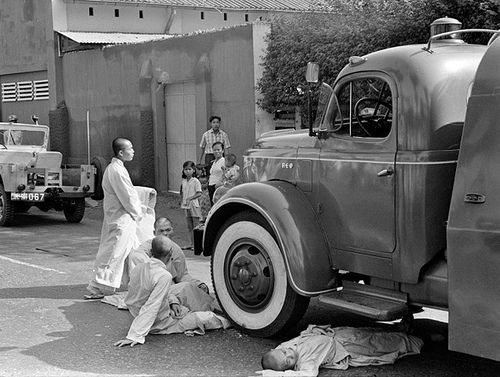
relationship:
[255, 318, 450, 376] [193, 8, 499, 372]
man under truck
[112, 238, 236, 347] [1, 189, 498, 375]
man on ground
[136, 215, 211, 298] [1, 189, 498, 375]
man on ground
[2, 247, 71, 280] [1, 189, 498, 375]
line on ground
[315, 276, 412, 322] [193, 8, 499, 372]
running board on truck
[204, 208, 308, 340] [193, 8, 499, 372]
tire on truck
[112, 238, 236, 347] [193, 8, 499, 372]
man near truck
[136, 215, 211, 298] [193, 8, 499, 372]
man near truck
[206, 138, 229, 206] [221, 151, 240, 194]
woman holding baby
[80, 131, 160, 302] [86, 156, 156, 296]
man wearing robe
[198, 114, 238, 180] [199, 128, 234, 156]
man wearing shirt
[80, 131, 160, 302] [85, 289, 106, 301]
man wearing sandals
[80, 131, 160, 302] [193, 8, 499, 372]
man looking at truck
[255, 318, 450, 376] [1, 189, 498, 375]
man on ground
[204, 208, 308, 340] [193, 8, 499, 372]
wheel on truck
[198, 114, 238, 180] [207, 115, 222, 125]
man with hair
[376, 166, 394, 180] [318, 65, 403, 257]
handle on door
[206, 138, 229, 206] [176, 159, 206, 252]
woman near child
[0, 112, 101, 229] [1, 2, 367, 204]
jeep near building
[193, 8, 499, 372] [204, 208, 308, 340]
truck has tire